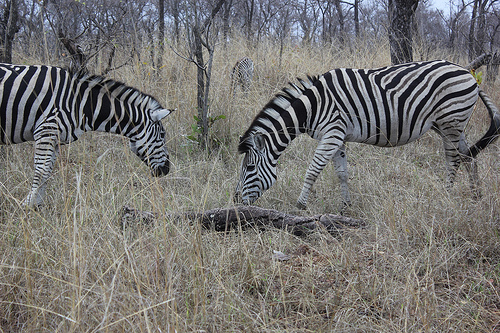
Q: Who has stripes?
A: The zebra.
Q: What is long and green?
A: The grass.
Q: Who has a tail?
A: Both zebra.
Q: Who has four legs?
A: One zebra.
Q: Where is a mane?
A: On zebra's necks.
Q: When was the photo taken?
A: During the daytime.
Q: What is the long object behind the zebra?
A: A tail.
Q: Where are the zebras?
A: In the grass.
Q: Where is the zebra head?
A: Near the log.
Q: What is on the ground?
A: A log.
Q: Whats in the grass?
A: Two zebras.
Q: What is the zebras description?
A: Black and white stripes.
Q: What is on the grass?
A: Log.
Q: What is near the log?
A: Tall grass.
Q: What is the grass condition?
A: Dry.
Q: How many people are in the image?
A: 0.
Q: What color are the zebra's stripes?
A: Black.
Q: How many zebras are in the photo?
A: 2.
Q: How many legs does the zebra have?
A: 4.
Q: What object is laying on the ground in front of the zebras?
A: A log.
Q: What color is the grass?
A: Green.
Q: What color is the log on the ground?
A: Brown.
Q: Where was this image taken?
A: In a zoo.